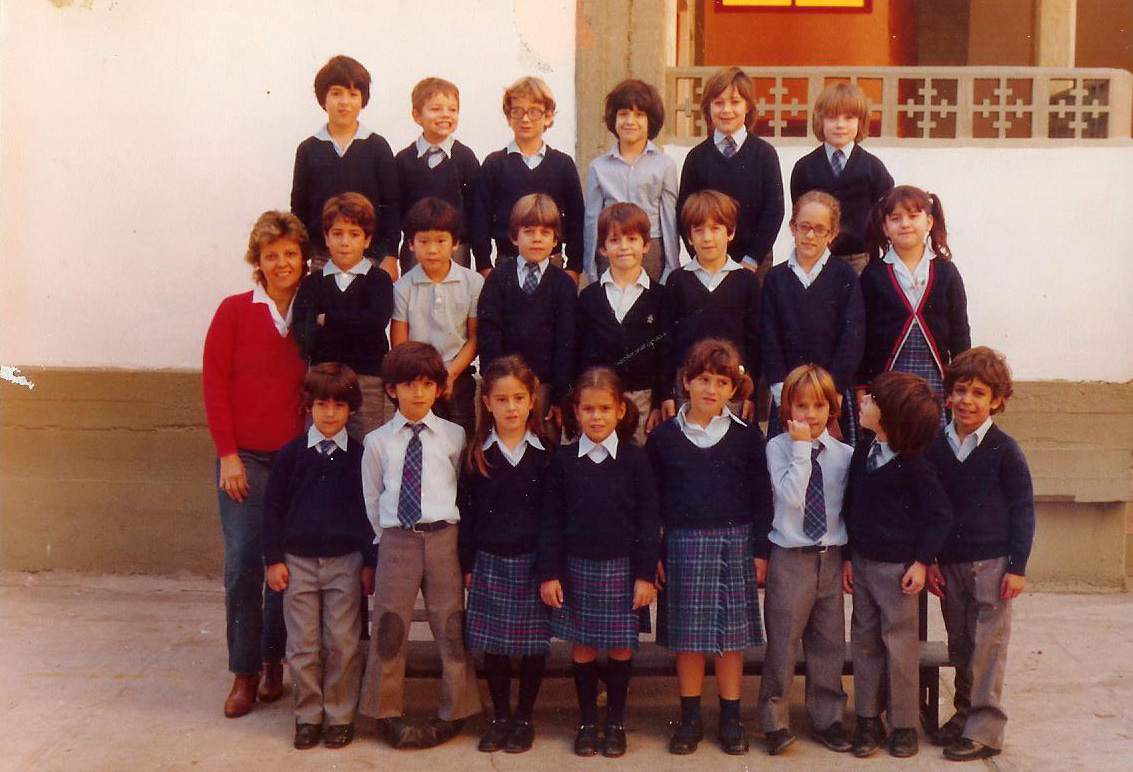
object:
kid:
[926, 346, 1038, 762]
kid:
[842, 371, 954, 758]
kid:
[755, 362, 854, 756]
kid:
[533, 367, 660, 758]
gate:
[664, 0, 1131, 148]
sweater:
[844, 434, 956, 565]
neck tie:
[804, 443, 828, 542]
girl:
[457, 354, 556, 754]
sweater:
[455, 438, 554, 576]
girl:
[643, 336, 774, 754]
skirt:
[655, 523, 765, 660]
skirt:
[551, 555, 650, 654]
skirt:
[464, 549, 553, 656]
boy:
[582, 78, 680, 285]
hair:
[601, 78, 664, 141]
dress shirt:
[582, 139, 680, 286]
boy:
[390, 196, 486, 444]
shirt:
[392, 257, 484, 372]